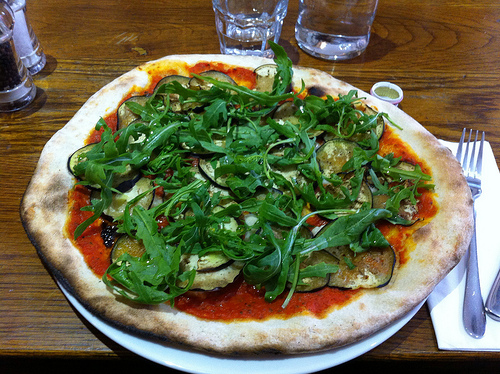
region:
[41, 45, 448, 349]
A vegetable pizza on a white plate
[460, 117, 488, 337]
A stainless steel fork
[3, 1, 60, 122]
Salt and pepper shakers on the table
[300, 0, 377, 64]
A glass of water on a table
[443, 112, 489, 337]
the fork is on a napkin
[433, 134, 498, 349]
The napkin is folded in half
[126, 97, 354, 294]
Fresh greens on a pizza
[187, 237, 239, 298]
Sliced eggplant on a pizza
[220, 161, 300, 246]
Looks like dandelion greens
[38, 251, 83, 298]
The crust is slightly burned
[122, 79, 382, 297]
green vegetables on pizza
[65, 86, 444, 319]
orange sauce on pizza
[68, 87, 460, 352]
black and light brown pizza crust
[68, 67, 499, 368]
pizza crust is well cooked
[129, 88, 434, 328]
leafy vegetables on pizza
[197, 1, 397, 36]
two glasses in front of pizza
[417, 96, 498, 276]
fork to right of pizza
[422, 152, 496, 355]
white napkin under fork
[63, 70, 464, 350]
pizza on white plate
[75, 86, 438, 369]
white plate on brown wooden table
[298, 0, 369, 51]
a glass on the table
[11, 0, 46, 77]
a salt shaker on the table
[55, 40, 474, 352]
a pizza on a plate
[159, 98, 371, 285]
basil on the pizza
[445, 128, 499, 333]
a fork on a napkin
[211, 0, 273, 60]
another glass on the table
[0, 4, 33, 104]
perhaps a pepper mill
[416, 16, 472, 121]
a dark wood table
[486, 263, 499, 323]
the handle of another utensil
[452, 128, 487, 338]
a shiny fork to eat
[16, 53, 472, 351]
a vegetarian pizza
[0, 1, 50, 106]
salt and pepper shakers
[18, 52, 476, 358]
a big round pizza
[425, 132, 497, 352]
a folded white napkin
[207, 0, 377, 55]
two clear empty glasses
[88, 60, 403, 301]
small leafy green spinach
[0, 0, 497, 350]
a brown wooded table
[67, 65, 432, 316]
red tomato pizza sauce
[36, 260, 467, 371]
a round white plate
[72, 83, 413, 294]
green vegetable on the pizza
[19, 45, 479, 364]
the crust is brown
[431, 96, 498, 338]
fork laying on napkin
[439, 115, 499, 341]
fork is next to pizza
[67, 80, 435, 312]
pizza sauce under vegetable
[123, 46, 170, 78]
tomato sauce on crust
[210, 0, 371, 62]
glass cups near pizza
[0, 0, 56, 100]
salt and pepper shaker near pizza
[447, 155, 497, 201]
light shining on fork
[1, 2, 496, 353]
table is made of wood